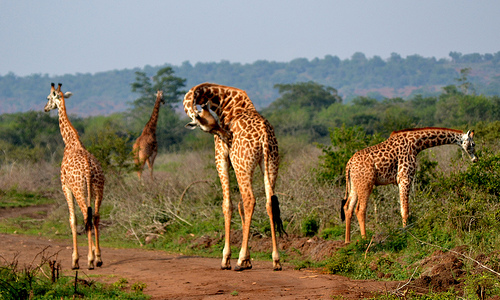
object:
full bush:
[88, 122, 145, 193]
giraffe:
[181, 82, 287, 271]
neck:
[183, 82, 226, 114]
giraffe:
[44, 80, 105, 270]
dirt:
[6, 245, 363, 299]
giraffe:
[343, 126, 478, 241]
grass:
[428, 159, 484, 215]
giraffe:
[133, 89, 167, 180]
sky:
[0, 0, 500, 78]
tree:
[132, 62, 184, 117]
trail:
[6, 196, 387, 298]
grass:
[5, 135, 385, 245]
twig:
[45, 255, 66, 282]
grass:
[5, 260, 143, 298]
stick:
[411, 231, 500, 290]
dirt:
[399, 241, 488, 292]